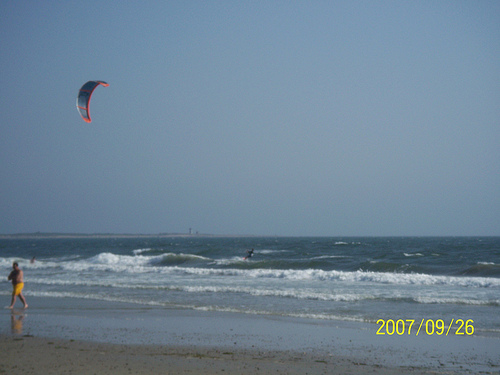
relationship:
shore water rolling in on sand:
[0, 276, 499, 347] [47, 282, 492, 371]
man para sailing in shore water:
[244, 248, 254, 261] [0, 276, 499, 347]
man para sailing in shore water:
[8, 259, 28, 311] [0, 276, 499, 347]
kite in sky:
[60, 72, 122, 129] [0, 0, 499, 234]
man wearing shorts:
[2, 257, 27, 313] [8, 279, 26, 298]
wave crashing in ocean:
[330, 237, 371, 247] [2, 236, 498, 305]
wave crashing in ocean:
[92, 248, 213, 265] [2, 236, 498, 305]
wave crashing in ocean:
[250, 247, 295, 253] [2, 236, 498, 305]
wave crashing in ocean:
[8, 266, 497, 290] [2, 236, 498, 305]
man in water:
[244, 248, 254, 261] [3, 225, 497, 325]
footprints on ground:
[141, 336, 318, 373] [4, 265, 459, 369]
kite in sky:
[74, 77, 109, 123] [210, 124, 325, 208]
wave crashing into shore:
[8, 266, 497, 290] [38, 298, 378, 365]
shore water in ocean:
[0, 276, 499, 347] [5, 234, 484, 325]